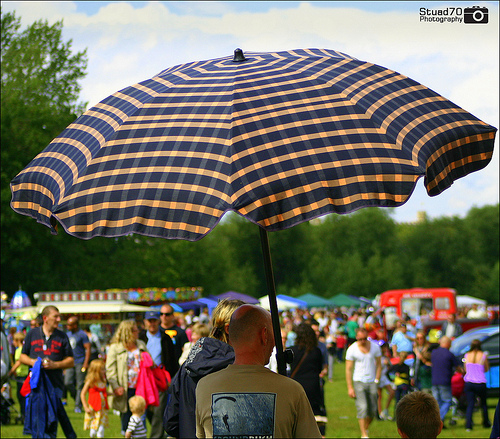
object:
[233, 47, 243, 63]
knob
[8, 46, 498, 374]
umbrella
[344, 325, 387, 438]
people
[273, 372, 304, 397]
shoulder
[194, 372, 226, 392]
shoulder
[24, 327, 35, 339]
shoulder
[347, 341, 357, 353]
shoulder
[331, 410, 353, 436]
green grass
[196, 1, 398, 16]
sky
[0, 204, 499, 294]
forest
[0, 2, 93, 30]
cloudy sky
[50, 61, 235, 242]
umbrella part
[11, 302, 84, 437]
man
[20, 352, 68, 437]
jacket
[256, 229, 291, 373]
handle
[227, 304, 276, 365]
head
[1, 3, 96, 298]
tree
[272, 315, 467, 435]
lawn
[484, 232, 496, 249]
green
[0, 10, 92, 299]
trees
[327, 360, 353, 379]
grass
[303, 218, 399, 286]
leaves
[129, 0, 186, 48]
clouds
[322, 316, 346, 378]
people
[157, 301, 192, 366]
people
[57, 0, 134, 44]
sky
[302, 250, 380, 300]
trees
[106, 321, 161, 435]
woman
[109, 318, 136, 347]
hair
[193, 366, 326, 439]
back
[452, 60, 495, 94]
sky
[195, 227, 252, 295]
tree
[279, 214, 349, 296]
tree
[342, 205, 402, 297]
tree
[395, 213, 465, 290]
tree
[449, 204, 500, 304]
tree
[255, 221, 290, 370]
umbrella part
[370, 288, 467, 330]
bus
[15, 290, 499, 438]
crowd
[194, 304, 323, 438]
man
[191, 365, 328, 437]
t-shirt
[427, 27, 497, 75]
clouds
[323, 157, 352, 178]
dots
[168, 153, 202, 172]
dots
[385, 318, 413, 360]
person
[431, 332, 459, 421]
person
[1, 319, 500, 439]
land